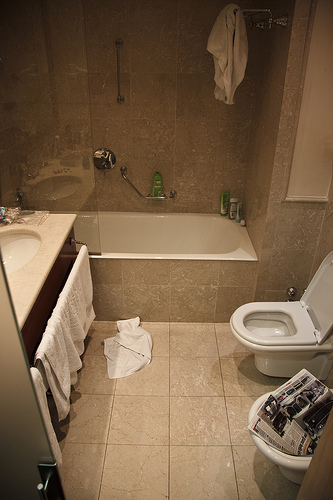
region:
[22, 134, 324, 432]
A beige bathroom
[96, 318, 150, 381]
A white towel on floor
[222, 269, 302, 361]
A white toilet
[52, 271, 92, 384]
A white towel hanging on towel bar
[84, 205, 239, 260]
A white bathtub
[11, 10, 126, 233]
A glass tub surround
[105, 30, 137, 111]
A chrome safety bar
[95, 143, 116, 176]
A chrome contol knob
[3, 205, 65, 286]
A beige counter and white sink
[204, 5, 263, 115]
towel hanging in the shower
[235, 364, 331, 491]
papers in a white basket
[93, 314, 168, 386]
white towel laying on the floor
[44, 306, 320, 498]
tiles on the floor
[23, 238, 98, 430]
white towels hanging on a rod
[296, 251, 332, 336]
toilet lid is up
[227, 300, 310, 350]
toilet seat is down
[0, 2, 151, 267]
sliding glass door on the tub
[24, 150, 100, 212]
reflection in the glass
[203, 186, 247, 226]
products on the corner of the tub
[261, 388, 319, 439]
newspapers in a basin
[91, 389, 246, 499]
cream tiles on the floor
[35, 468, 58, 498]
the handle of a door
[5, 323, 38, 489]
a door to the bathroom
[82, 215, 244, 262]
a white bath basin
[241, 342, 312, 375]
a white toilet bowl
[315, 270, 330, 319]
the lid of a toilet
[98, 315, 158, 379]
towel on bathroom floor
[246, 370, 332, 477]
container full of reading material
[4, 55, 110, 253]
glass shower door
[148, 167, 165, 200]
shampoo in a green bottle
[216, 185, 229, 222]
conditioner in a green bottle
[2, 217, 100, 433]
vanity with towels hanging in front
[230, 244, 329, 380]
toilet with the lid up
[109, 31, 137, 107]
handle on wall of shower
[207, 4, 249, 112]
towel hanging from showerhead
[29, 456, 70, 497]
handle of a bathroom door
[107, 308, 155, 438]
a towel laying on the floor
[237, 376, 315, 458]
magazines in a trashcan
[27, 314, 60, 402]
towels hanging on a towel rack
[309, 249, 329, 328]
toilet lid lifted up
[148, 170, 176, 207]
shampoo sitting on a safety rail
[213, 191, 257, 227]
soaps sitting on the edge of a tub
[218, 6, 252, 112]
a towel hanging in the shower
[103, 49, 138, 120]
a safety rail attached to the wall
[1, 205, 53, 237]
plastic sitting on a vanity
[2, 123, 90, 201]
shower glass door making a reflection